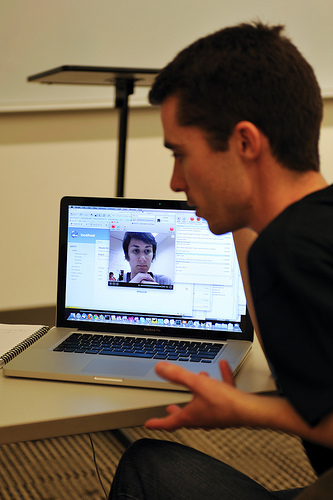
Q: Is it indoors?
A: Yes, it is indoors.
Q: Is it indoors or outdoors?
A: It is indoors.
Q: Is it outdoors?
A: No, it is indoors.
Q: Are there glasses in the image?
A: No, there are no glasses.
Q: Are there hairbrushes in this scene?
A: No, there are no hairbrushes.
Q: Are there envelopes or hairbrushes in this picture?
A: No, there are no hairbrushes or envelopes.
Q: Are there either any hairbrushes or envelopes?
A: No, there are no hairbrushes or envelopes.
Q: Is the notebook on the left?
A: Yes, the notebook is on the left of the image.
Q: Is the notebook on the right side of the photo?
A: No, the notebook is on the left of the image.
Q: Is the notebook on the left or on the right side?
A: The notebook is on the left of the image.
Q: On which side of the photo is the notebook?
A: The notebook is on the left of the image.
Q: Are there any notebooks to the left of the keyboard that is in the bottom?
A: Yes, there is a notebook to the left of the keyboard.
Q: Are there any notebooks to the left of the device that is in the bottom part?
A: Yes, there is a notebook to the left of the keyboard.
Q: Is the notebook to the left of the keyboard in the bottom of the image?
A: Yes, the notebook is to the left of the keyboard.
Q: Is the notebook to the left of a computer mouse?
A: No, the notebook is to the left of the keyboard.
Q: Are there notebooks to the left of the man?
A: Yes, there is a notebook to the left of the man.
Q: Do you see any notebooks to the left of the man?
A: Yes, there is a notebook to the left of the man.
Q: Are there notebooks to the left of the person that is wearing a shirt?
A: Yes, there is a notebook to the left of the man.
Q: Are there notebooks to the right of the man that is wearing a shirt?
A: No, the notebook is to the left of the man.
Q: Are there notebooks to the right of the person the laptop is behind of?
A: No, the notebook is to the left of the man.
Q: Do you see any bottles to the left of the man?
A: No, there is a notebook to the left of the man.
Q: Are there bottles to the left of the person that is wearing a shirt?
A: No, there is a notebook to the left of the man.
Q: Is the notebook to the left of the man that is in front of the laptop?
A: Yes, the notebook is to the left of the man.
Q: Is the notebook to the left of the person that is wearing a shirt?
A: Yes, the notebook is to the left of the man.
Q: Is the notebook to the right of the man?
A: No, the notebook is to the left of the man.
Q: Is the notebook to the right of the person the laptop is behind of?
A: No, the notebook is to the left of the man.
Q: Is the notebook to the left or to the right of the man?
A: The notebook is to the left of the man.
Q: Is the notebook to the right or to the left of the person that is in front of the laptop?
A: The notebook is to the left of the man.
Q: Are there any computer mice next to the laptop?
A: No, there is a notebook next to the laptop.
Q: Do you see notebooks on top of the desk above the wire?
A: Yes, there is a notebook on top of the desk.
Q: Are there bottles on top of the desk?
A: No, there is a notebook on top of the desk.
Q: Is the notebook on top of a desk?
A: Yes, the notebook is on top of a desk.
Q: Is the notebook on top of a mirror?
A: No, the notebook is on top of a desk.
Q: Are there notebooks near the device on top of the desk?
A: Yes, there is a notebook near the laptop.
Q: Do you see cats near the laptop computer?
A: No, there is a notebook near the laptop computer.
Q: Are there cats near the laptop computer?
A: No, there is a notebook near the laptop computer.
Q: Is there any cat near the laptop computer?
A: No, there is a notebook near the laptop computer.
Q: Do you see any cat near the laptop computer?
A: No, there is a notebook near the laptop computer.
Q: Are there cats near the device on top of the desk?
A: No, there is a notebook near the laptop computer.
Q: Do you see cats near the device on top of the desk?
A: No, there is a notebook near the laptop computer.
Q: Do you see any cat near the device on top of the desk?
A: No, there is a notebook near the laptop computer.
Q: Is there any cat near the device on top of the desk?
A: No, there is a notebook near the laptop computer.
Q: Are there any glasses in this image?
A: No, there are no glasses.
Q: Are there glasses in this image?
A: No, there are no glasses.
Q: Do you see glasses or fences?
A: No, there are no glasses or fences.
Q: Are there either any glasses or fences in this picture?
A: No, there are no glasses or fences.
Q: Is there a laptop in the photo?
A: Yes, there is a laptop.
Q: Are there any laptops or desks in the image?
A: Yes, there is a laptop.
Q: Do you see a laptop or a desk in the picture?
A: Yes, there is a laptop.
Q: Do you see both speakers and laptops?
A: No, there is a laptop but no speakers.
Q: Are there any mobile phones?
A: No, there are no mobile phones.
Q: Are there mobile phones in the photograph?
A: No, there are no mobile phones.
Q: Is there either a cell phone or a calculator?
A: No, there are no cell phones or calculators.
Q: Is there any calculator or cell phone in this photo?
A: No, there are no cell phones or calculators.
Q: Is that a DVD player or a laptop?
A: That is a laptop.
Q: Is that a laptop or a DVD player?
A: That is a laptop.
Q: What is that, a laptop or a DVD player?
A: That is a laptop.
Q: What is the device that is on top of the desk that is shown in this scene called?
A: The device is a laptop.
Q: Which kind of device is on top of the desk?
A: The device is a laptop.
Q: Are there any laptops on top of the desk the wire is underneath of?
A: Yes, there is a laptop on top of the desk.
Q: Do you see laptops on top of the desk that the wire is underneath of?
A: Yes, there is a laptop on top of the desk.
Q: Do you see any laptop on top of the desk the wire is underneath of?
A: Yes, there is a laptop on top of the desk.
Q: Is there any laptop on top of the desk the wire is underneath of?
A: Yes, there is a laptop on top of the desk.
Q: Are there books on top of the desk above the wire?
A: No, there is a laptop on top of the desk.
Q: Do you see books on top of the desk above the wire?
A: No, there is a laptop on top of the desk.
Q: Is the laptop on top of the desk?
A: Yes, the laptop is on top of the desk.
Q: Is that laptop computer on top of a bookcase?
A: No, the laptop computer is on top of the desk.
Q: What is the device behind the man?
A: The device is a laptop.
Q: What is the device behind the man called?
A: The device is a laptop.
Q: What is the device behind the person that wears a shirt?
A: The device is a laptop.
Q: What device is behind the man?
A: The device is a laptop.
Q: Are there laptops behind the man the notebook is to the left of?
A: Yes, there is a laptop behind the man.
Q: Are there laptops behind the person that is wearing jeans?
A: Yes, there is a laptop behind the man.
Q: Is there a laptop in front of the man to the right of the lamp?
A: No, the laptop is behind the man.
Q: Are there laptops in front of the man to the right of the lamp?
A: No, the laptop is behind the man.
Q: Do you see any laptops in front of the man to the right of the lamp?
A: No, the laptop is behind the man.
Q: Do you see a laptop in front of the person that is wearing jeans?
A: No, the laptop is behind the man.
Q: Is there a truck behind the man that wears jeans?
A: No, there is a laptop behind the man.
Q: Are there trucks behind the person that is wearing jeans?
A: No, there is a laptop behind the man.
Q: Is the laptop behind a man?
A: Yes, the laptop is behind a man.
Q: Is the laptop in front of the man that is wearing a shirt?
A: No, the laptop is behind the man.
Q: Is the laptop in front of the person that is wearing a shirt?
A: No, the laptop is behind the man.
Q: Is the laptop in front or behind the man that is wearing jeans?
A: The laptop is behind the man.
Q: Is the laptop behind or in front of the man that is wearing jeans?
A: The laptop is behind the man.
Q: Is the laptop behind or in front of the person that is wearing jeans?
A: The laptop is behind the man.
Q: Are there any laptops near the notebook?
A: Yes, there is a laptop near the notebook.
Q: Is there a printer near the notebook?
A: No, there is a laptop near the notebook.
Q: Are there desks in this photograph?
A: Yes, there is a desk.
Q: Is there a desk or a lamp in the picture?
A: Yes, there is a desk.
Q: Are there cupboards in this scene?
A: No, there are no cupboards.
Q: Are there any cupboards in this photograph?
A: No, there are no cupboards.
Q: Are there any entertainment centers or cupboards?
A: No, there are no cupboards or entertainment centers.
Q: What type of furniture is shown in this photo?
A: The furniture is a desk.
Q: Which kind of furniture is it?
A: The piece of furniture is a desk.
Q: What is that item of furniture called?
A: This is a desk.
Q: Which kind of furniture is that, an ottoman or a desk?
A: This is a desk.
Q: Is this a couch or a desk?
A: This is a desk.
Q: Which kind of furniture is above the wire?
A: The piece of furniture is a desk.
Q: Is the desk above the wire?
A: Yes, the desk is above the wire.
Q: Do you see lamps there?
A: Yes, there is a lamp.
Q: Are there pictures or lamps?
A: Yes, there is a lamp.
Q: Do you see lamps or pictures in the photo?
A: Yes, there is a lamp.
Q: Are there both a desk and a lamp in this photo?
A: Yes, there are both a lamp and a desk.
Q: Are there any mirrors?
A: No, there are no mirrors.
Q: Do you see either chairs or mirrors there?
A: No, there are no mirrors or chairs.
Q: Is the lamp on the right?
A: No, the lamp is on the left of the image.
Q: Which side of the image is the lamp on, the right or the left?
A: The lamp is on the left of the image.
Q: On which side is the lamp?
A: The lamp is on the left of the image.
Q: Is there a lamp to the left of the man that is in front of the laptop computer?
A: Yes, there is a lamp to the left of the man.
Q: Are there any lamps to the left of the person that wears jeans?
A: Yes, there is a lamp to the left of the man.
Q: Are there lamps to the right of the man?
A: No, the lamp is to the left of the man.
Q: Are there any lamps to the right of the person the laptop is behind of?
A: No, the lamp is to the left of the man.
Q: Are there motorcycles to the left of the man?
A: No, there is a lamp to the left of the man.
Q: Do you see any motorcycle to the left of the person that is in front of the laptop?
A: No, there is a lamp to the left of the man.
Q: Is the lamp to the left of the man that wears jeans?
A: Yes, the lamp is to the left of the man.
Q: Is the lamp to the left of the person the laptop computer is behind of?
A: Yes, the lamp is to the left of the man.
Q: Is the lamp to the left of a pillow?
A: No, the lamp is to the left of the man.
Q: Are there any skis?
A: No, there are no skis.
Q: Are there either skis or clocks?
A: No, there are no skis or clocks.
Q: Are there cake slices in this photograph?
A: No, there are no cake slices.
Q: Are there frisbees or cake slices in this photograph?
A: No, there are no cake slices or frisbees.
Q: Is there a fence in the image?
A: No, there are no fences.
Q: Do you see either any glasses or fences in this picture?
A: No, there are no fences or glasses.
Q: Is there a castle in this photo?
A: No, there are no castles.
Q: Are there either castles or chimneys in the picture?
A: No, there are no castles or chimneys.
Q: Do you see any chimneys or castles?
A: No, there are no castles or chimneys.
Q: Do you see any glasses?
A: No, there are no glasses.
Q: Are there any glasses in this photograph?
A: No, there are no glasses.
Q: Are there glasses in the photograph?
A: No, there are no glasses.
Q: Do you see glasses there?
A: No, there are no glasses.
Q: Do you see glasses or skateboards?
A: No, there are no glasses or skateboards.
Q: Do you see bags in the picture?
A: No, there are no bags.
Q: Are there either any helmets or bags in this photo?
A: No, there are no bags or helmets.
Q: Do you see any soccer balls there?
A: No, there are no soccer balls.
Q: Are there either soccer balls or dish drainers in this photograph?
A: No, there are no soccer balls or dish drainers.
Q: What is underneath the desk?
A: The wire is underneath the desk.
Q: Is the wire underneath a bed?
A: No, the wire is underneath the desk.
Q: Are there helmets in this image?
A: No, there are no helmets.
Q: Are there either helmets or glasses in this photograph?
A: No, there are no helmets or glasses.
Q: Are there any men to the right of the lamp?
A: Yes, there is a man to the right of the lamp.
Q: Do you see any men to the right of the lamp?
A: Yes, there is a man to the right of the lamp.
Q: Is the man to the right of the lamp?
A: Yes, the man is to the right of the lamp.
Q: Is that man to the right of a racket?
A: No, the man is to the right of the lamp.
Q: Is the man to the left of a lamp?
A: No, the man is to the right of a lamp.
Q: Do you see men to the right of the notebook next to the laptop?
A: Yes, there is a man to the right of the notebook.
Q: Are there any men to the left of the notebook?
A: No, the man is to the right of the notebook.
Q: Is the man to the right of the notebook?
A: Yes, the man is to the right of the notebook.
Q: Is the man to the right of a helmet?
A: No, the man is to the right of the notebook.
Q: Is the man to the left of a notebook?
A: No, the man is to the right of a notebook.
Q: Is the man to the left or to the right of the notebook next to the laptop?
A: The man is to the right of the notebook.